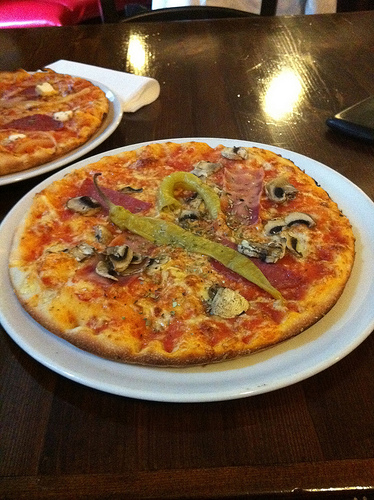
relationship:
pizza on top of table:
[4, 129, 360, 375] [177, 21, 320, 111]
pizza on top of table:
[1, 64, 126, 140] [177, 21, 320, 111]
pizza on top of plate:
[4, 129, 360, 375] [335, 182, 352, 197]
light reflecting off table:
[260, 53, 310, 110] [177, 21, 320, 111]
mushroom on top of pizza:
[264, 185, 294, 202] [4, 129, 360, 375]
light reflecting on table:
[260, 53, 310, 110] [177, 21, 320, 111]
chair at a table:
[95, 1, 280, 15] [177, 21, 320, 111]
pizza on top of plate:
[1, 64, 126, 140] [109, 103, 117, 115]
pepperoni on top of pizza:
[109, 188, 135, 204] [4, 129, 360, 375]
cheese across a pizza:
[47, 259, 67, 275] [4, 129, 360, 375]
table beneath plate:
[177, 21, 320, 111] [335, 182, 352, 197]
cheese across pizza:
[47, 259, 67, 275] [4, 129, 360, 375]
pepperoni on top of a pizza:
[109, 188, 135, 204] [4, 129, 360, 375]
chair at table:
[95, 1, 280, 15] [177, 21, 320, 111]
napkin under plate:
[107, 65, 147, 92] [0, 69, 125, 185]